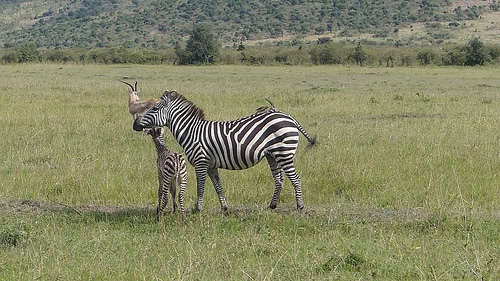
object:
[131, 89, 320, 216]
zebra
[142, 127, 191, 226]
zebra